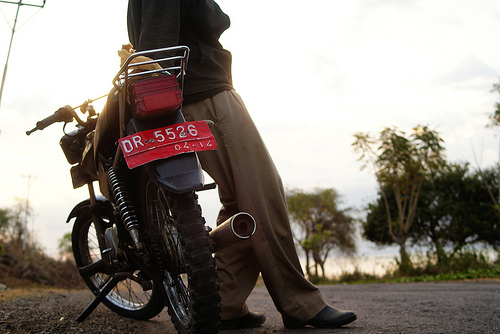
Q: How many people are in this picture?
A: One.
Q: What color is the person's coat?
A: Brown.